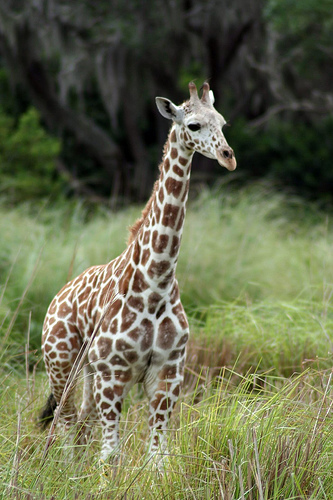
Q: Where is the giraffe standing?
A: On the grass.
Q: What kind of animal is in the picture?
A: A giraffe.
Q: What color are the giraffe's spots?
A: Brown.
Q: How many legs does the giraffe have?
A: Four.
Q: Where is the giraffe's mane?
A: Neck.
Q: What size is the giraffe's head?
A: Small.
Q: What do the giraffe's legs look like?
A: Long.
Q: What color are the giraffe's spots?
A: Brown.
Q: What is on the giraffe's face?
A: Ears, eyes, and nose.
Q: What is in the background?
A: Tree.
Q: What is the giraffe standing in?
A: Grass.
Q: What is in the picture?
A: A giraffe.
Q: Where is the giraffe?
A: Wilderness.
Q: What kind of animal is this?
A: Giraffe.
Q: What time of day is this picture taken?
A: Daylight hours.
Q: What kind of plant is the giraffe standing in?
A: Grass.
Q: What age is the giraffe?
A: Juvenile.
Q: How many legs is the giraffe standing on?
A: 4.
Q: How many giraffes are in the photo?
A: 1.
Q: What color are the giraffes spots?
A: Brown.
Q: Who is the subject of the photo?
A: The giraffe.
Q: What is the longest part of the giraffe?
A: The neck.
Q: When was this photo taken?
A: During the day.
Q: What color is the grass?
A: Green.